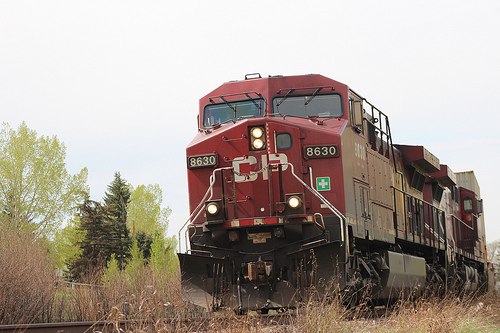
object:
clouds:
[137, 67, 181, 119]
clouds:
[393, 77, 428, 133]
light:
[206, 202, 222, 217]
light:
[250, 126, 266, 138]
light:
[250, 138, 266, 151]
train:
[176, 72, 496, 316]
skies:
[33, 50, 60, 72]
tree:
[0, 120, 89, 277]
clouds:
[96, 0, 155, 25]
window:
[271, 92, 345, 118]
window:
[202, 96, 267, 128]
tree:
[56, 172, 132, 286]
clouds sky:
[174, 90, 194, 136]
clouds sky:
[232, 0, 274, 36]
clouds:
[102, 142, 179, 163]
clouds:
[409, 0, 479, 34]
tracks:
[0, 305, 402, 333]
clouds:
[0, 51, 36, 126]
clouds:
[464, 95, 498, 145]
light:
[287, 195, 303, 210]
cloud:
[299, 6, 355, 71]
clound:
[75, 121, 94, 174]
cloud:
[0, 0, 51, 18]